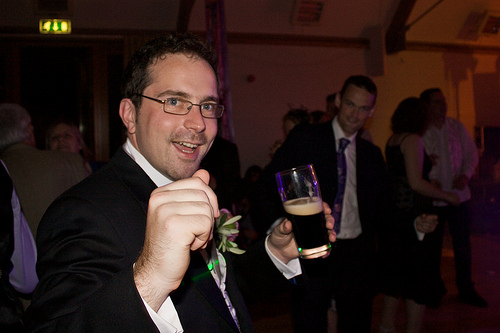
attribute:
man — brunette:
[21, 32, 336, 332]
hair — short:
[153, 32, 218, 64]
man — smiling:
[255, 72, 423, 314]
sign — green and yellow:
[28, 6, 92, 63]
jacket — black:
[31, 147, 305, 331]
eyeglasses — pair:
[145, 93, 219, 120]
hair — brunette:
[119, 31, 219, 106]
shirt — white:
[330, 116, 361, 240]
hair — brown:
[127, 27, 250, 128]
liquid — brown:
[289, 192, 339, 270]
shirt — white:
[320, 120, 391, 260]